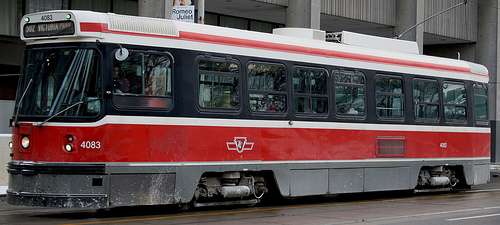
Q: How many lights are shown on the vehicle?
A: Three.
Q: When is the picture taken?
A: Day time.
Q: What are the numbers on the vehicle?
A: 4083.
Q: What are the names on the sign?
A: Romeo juliet.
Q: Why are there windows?
A: To see outside.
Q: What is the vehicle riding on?
A: Tracks.